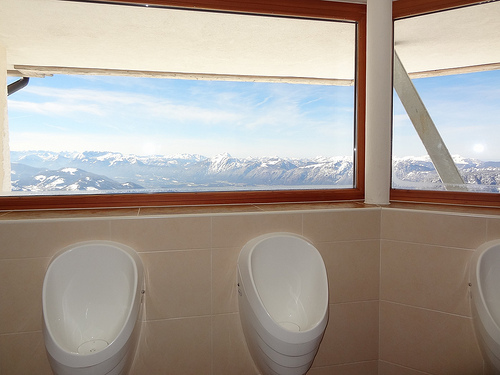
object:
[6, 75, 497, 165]
sky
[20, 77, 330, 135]
clouds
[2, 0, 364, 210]
frame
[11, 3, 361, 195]
window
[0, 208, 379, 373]
wall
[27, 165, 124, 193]
mountains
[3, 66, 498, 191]
outside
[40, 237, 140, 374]
urinal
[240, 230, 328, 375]
urinal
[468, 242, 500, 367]
urinal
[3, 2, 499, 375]
bathroom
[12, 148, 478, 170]
snow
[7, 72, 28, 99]
support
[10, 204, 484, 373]
grout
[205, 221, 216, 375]
crack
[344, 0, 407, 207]
corner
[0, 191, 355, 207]
edge